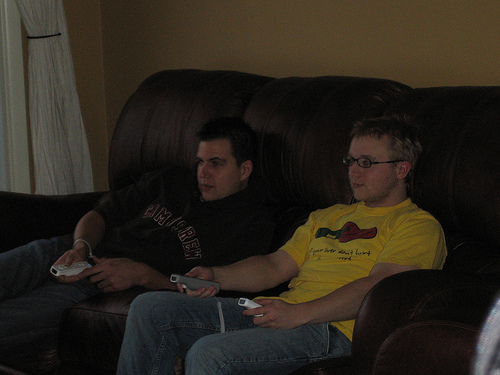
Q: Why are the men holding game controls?
A: Playing game.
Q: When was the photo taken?
A: Daylight.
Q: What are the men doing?
A: Playing Wii.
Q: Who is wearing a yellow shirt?
A: Man with glasses.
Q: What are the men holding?
A: Wii remotes.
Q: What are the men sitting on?
A: Loveseat.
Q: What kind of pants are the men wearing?
A: Blue jeans.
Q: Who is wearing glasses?
A: Man in yellow shirt.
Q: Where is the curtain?
A: In the corner.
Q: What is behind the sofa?
A: A wall.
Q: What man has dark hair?
A: Man on left.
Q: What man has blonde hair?
A: Man on right.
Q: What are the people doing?
A: Playing video games.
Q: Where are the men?
A: On the couch.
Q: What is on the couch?
A: Two men.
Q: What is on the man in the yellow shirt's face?
A: Glasses.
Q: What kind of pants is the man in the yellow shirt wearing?
A: Jeans.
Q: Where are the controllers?
A: In the men's hands.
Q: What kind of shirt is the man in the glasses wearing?
A: T shirt.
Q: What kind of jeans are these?
A: Light blue.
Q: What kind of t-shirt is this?
A: A yellow t-shirt.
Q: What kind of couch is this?
A: A brown couch.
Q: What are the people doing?
A: Playing.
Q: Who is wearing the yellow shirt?
A: The man with glasses.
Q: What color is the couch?
A: Brown.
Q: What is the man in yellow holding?
A: A remote control.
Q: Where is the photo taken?
A: Inside a room.